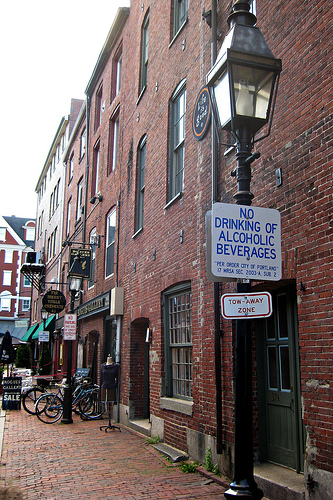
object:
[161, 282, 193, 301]
lines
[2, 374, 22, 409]
sign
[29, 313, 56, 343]
awnings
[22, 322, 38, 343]
awnings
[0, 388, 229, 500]
sidewalk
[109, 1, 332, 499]
building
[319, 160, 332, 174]
brick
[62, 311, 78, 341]
sign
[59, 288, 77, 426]
pole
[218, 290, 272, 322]
sign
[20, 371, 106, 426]
row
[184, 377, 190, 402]
window